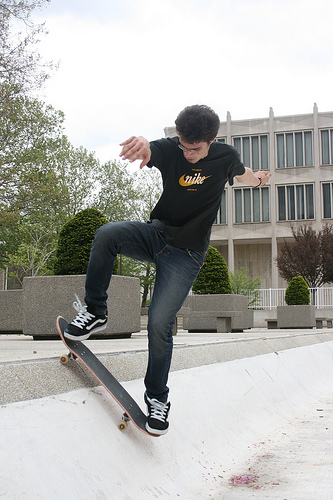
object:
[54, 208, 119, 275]
plant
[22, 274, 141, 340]
block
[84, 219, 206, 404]
jeans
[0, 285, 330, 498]
concrete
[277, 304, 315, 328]
planter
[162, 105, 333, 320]
building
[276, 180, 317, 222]
windows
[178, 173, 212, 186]
letter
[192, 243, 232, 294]
pamt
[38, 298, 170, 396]
white railing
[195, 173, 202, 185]
k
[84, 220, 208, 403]
dark jeans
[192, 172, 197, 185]
letter i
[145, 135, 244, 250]
shirt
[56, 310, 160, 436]
scateboard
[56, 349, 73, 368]
wheel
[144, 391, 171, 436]
shoe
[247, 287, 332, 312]
fence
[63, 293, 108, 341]
shoe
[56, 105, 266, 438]
boy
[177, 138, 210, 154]
glasses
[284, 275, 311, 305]
plant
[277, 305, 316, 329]
block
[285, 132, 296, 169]
windows